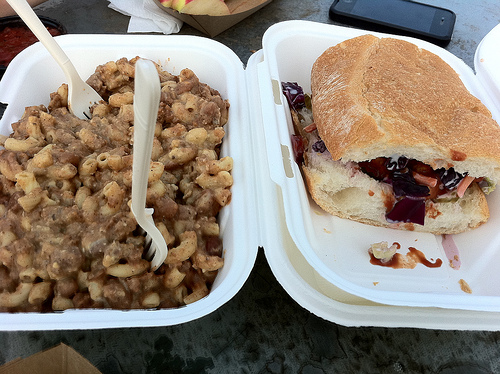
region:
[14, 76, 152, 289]
the food is brown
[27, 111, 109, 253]
the food is brown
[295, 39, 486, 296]
sandwich in a to-go box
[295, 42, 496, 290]
a piece of sandwich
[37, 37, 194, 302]
forks on the food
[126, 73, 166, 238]
this is a fork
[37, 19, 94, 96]
this is a fork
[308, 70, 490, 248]
this is a sandwitch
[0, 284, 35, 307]
this is a piece of macoroni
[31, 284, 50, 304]
this is a piece of macoroni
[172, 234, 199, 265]
this is a piece of macoroni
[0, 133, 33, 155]
this is a piece of macoroni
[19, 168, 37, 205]
this is a piece of macoroni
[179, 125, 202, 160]
this is a piece of macoroni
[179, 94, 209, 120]
this is a piece of macoroni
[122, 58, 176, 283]
white plastic fork in some food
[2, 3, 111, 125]
white plastic fork in some food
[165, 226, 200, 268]
small piece of cooked macaroni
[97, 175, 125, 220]
small piece of cooked macaroni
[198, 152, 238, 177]
small piece of cooked macaroni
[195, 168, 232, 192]
small piece of cooked macaroni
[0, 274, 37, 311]
small piece of cooked macaroni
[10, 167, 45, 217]
small piece of cooked macaroni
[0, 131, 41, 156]
small piece of cooked macaroni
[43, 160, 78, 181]
small piece of cooked macaroni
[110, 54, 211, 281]
a plastic fork stuck in food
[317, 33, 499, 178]
the top bread piece of a sandwich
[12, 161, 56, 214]
a piece of macaroni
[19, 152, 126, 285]
a casserole with noodles and meat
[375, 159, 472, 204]
meat in a sauce as part of a sandwich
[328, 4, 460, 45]
a black smartphone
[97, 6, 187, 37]
a white paper napkin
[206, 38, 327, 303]
a styrofoam box for carrying food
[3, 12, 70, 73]
sauce in black plastic dish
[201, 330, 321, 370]
a marble tabletop